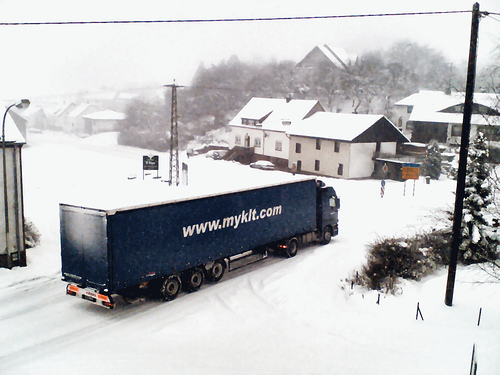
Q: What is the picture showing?
A: It is showing a road.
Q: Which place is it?
A: It is a road.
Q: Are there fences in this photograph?
A: No, there are no fences.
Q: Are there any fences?
A: No, there are no fences.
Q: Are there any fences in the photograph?
A: No, there are no fences.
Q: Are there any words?
A: Yes, there are words.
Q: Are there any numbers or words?
A: Yes, there are words.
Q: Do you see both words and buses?
A: No, there are words but no buses.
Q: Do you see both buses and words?
A: No, there are words but no buses.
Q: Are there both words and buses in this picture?
A: No, there are words but no buses.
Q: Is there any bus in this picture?
A: No, there are no buses.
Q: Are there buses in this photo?
A: No, there are no buses.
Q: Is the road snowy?
A: Yes, the road is snowy.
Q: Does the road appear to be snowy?
A: Yes, the road is snowy.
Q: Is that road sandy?
A: No, the road is snowy.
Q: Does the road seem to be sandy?
A: No, the road is snowy.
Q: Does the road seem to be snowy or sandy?
A: The road is snowy.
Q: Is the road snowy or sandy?
A: The road is snowy.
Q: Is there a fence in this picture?
A: No, there are no fences.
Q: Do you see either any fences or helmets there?
A: No, there are no fences or helmets.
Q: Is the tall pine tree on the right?
A: Yes, the pine tree is on the right of the image.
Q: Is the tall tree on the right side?
A: Yes, the pine tree is on the right of the image.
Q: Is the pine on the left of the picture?
A: No, the pine is on the right of the image.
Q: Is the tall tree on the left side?
A: No, the pine is on the right of the image.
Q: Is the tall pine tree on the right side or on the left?
A: The pine tree is on the right of the image.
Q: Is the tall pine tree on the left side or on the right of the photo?
A: The pine tree is on the right of the image.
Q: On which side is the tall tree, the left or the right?
A: The pine tree is on the right of the image.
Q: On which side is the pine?
A: The pine is on the right of the image.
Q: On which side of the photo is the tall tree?
A: The pine is on the right of the image.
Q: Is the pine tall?
A: Yes, the pine is tall.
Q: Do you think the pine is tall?
A: Yes, the pine is tall.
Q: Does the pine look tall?
A: Yes, the pine is tall.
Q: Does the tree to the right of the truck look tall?
A: Yes, the pine is tall.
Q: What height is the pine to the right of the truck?
A: The pine tree is tall.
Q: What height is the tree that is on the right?
A: The pine tree is tall.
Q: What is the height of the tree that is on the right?
A: The pine tree is tall.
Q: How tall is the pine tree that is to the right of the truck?
A: The pine is tall.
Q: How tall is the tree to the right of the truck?
A: The pine is tall.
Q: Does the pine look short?
A: No, the pine is tall.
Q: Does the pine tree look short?
A: No, the pine tree is tall.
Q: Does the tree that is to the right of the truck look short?
A: No, the pine tree is tall.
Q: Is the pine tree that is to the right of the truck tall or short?
A: The pine is tall.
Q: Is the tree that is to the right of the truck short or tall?
A: The pine is tall.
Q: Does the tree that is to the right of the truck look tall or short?
A: The pine is tall.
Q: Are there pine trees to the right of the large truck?
A: Yes, there is a pine tree to the right of the truck.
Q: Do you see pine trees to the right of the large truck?
A: Yes, there is a pine tree to the right of the truck.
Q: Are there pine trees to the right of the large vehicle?
A: Yes, there is a pine tree to the right of the truck.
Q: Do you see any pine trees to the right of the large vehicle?
A: Yes, there is a pine tree to the right of the truck.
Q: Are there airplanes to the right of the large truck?
A: No, there is a pine tree to the right of the truck.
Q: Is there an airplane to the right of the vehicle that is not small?
A: No, there is a pine tree to the right of the truck.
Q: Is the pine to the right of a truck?
A: Yes, the pine is to the right of a truck.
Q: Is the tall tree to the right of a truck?
A: Yes, the pine is to the right of a truck.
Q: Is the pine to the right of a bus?
A: No, the pine is to the right of a truck.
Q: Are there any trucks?
A: Yes, there is a truck.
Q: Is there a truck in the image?
A: Yes, there is a truck.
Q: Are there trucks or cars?
A: Yes, there is a truck.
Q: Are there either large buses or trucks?
A: Yes, there is a large truck.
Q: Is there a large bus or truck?
A: Yes, there is a large truck.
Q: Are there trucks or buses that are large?
A: Yes, the truck is large.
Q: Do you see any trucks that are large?
A: Yes, there is a large truck.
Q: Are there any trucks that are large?
A: Yes, there is a truck that is large.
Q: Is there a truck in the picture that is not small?
A: Yes, there is a large truck.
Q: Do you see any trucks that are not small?
A: Yes, there is a large truck.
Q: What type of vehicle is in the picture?
A: The vehicle is a truck.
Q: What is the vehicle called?
A: The vehicle is a truck.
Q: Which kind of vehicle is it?
A: The vehicle is a truck.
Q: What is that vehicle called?
A: This is a truck.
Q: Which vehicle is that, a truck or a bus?
A: This is a truck.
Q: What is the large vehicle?
A: The vehicle is a truck.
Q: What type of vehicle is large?
A: The vehicle is a truck.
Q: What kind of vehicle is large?
A: The vehicle is a truck.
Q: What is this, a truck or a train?
A: This is a truck.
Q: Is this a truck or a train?
A: This is a truck.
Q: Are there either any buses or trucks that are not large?
A: No, there is a truck but it is large.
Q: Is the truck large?
A: Yes, the truck is large.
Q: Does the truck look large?
A: Yes, the truck is large.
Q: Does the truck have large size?
A: Yes, the truck is large.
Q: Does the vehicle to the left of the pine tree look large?
A: Yes, the truck is large.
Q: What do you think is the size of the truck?
A: The truck is large.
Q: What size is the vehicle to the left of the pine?
A: The truck is large.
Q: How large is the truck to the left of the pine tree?
A: The truck is large.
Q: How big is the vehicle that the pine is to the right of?
A: The truck is large.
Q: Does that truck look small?
A: No, the truck is large.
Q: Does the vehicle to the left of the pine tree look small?
A: No, the truck is large.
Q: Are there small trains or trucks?
A: No, there is a truck but it is large.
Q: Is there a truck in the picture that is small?
A: No, there is a truck but it is large.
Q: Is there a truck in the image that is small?
A: No, there is a truck but it is large.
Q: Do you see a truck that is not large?
A: No, there is a truck but it is large.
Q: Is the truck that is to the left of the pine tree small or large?
A: The truck is large.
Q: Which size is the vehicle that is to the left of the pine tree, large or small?
A: The truck is large.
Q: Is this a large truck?
A: Yes, this is a large truck.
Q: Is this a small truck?
A: No, this is a large truck.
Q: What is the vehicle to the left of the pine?
A: The vehicle is a truck.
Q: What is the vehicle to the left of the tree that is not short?
A: The vehicle is a truck.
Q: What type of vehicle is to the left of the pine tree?
A: The vehicle is a truck.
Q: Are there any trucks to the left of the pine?
A: Yes, there is a truck to the left of the pine.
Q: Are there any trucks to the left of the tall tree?
A: Yes, there is a truck to the left of the pine.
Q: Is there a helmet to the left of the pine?
A: No, there is a truck to the left of the pine.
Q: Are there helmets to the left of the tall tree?
A: No, there is a truck to the left of the pine.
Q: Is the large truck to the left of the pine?
A: Yes, the truck is to the left of the pine.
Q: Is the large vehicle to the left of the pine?
A: Yes, the truck is to the left of the pine.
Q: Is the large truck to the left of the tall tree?
A: Yes, the truck is to the left of the pine.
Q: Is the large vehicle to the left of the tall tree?
A: Yes, the truck is to the left of the pine.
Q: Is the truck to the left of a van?
A: No, the truck is to the left of the pine.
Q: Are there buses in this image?
A: No, there are no buses.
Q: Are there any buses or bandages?
A: No, there are no buses or bandages.